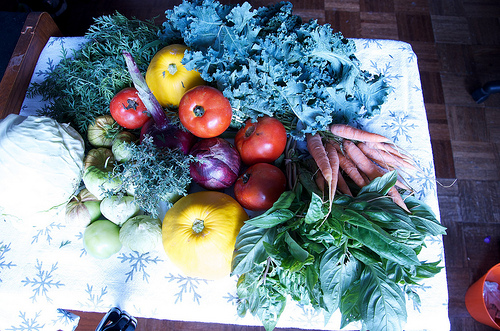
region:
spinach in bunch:
[166, 4, 391, 137]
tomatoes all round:
[108, 86, 285, 206]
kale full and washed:
[227, 171, 446, 329]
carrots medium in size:
[306, 121, 420, 215]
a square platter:
[2, 27, 455, 329]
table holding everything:
[1, 0, 448, 330]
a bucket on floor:
[464, 261, 498, 330]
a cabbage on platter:
[1, 112, 86, 216]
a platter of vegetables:
[1, 0, 446, 328]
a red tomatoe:
[174, 85, 231, 139]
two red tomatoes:
[180, 74, 291, 159]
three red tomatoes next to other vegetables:
[97, 70, 283, 155]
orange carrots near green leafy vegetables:
[299, 94, 420, 212]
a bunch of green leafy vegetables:
[253, 202, 429, 318]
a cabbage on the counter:
[2, 95, 83, 218]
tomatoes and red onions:
[172, 98, 284, 196]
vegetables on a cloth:
[52, 15, 432, 306]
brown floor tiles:
[420, 9, 499, 76]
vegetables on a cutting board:
[0, 26, 380, 309]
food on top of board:
[21, 28, 429, 312]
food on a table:
[3, 32, 423, 305]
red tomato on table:
[180, 83, 233, 137]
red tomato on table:
[239, 156, 286, 205]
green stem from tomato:
[239, 165, 248, 182]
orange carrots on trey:
[300, 120, 418, 211]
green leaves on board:
[252, 206, 433, 323]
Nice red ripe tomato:
[178, 90, 226, 137]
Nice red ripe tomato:
[239, 120, 289, 162]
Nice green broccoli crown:
[136, 149, 183, 196]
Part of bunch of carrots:
[306, 121, 418, 170]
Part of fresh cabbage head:
[4, 113, 81, 203]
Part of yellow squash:
[171, 210, 226, 247]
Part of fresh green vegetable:
[223, 31, 328, 88]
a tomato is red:
[177, 85, 227, 135]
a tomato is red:
[235, 117, 285, 165]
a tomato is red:
[231, 162, 282, 209]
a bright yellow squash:
[160, 190, 245, 286]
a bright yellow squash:
[145, 44, 205, 106]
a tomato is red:
[108, 87, 148, 128]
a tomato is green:
[80, 220, 121, 253]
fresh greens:
[233, 172, 437, 330]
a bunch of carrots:
[303, 123, 423, 210]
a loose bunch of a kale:
[159, 4, 390, 139]